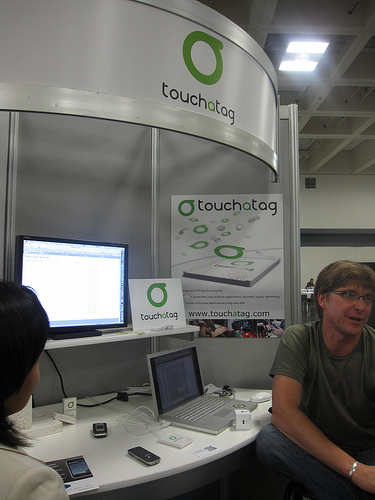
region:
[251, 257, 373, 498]
Man sitting at desk with crossed legs.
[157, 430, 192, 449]
Ipod lying on desk.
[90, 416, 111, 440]
Cell phone lying on desk.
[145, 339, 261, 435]
Laptop computer sitting on desk.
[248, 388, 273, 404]
White computer mouse lying on desk.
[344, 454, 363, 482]
Man wearing silver braclet on wrist.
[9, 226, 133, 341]
Computer monitor sitting on top shelf of desk.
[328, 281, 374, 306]
Man wearing eyeglasses over eyes.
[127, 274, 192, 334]
White and green sign sitting on top shelf of desk.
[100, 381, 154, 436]
Tangled electrical cords on top of desk.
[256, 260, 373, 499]
man wearing glasses is sitting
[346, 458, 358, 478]
man wearing silver bracelet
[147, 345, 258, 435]
open laptop on desk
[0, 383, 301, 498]
desk is white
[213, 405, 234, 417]
touchpad on laptop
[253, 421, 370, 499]
man wearing blue jeans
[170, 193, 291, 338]
poster hanging on wall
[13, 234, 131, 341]
monitor sitting on white shelf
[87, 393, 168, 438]
white tangled cable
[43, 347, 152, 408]
long black cord on desk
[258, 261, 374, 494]
man in a green shirt and blue jeans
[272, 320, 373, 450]
green t-shirt on a man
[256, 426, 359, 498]
the man's blue jeans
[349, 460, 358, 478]
silver bracelet on man's right wrist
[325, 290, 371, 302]
a pair of glasses on the man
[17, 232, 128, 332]
a computer monitor on a shelf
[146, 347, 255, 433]
a laptop computer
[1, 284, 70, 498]
woman with dark hair and white jacket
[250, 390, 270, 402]
white computer mouse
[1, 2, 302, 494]
trade show display for touchatag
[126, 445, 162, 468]
a cellphone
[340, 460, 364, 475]
man wearing a bracelet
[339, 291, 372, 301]
eyeglasses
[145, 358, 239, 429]
a laptop on the desk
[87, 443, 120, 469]
the desk is white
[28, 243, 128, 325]
a monitor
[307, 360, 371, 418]
man wearing a green shirt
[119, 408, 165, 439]
the chords are white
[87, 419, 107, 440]
a cellphone on the desk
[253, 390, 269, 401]
a white mouse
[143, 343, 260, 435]
silver lap top on a desk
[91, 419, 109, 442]
flip top cell phone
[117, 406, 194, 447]
white touch pad with cord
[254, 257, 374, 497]
man sitting on a chair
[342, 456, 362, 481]
silver bracelet on a wrist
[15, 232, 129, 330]
black lit up computer screen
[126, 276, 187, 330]
white and green touchatag sign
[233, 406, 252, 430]
white cube on a desk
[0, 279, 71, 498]
woman with black hair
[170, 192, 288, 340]
advertising sign on a wall